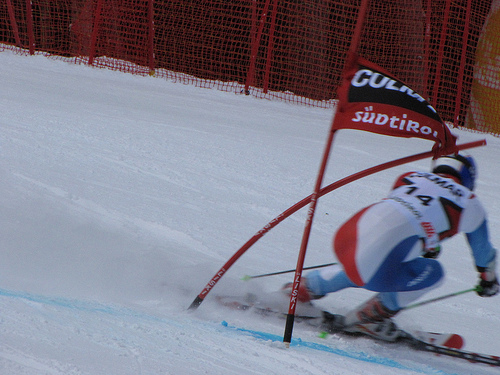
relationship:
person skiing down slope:
[264, 150, 499, 346] [4, 45, 499, 373]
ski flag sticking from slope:
[259, 3, 460, 343] [4, 45, 499, 373]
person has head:
[264, 150, 499, 346] [429, 148, 479, 192]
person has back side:
[264, 150, 499, 346] [332, 217, 409, 294]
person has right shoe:
[264, 150, 499, 346] [345, 301, 402, 341]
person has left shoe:
[264, 150, 499, 346] [280, 278, 319, 318]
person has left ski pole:
[264, 150, 499, 346] [244, 245, 341, 298]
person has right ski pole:
[264, 150, 499, 346] [321, 280, 481, 337]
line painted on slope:
[2, 283, 411, 372] [4, 45, 499, 373]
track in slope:
[11, 165, 230, 271] [4, 45, 499, 373]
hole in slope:
[142, 297, 167, 313] [4, 45, 499, 373]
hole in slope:
[47, 357, 62, 371] [4, 45, 499, 373]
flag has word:
[334, 54, 457, 155] [353, 101, 443, 140]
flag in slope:
[334, 54, 457, 155] [4, 45, 499, 373]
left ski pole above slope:
[244, 245, 341, 298] [4, 45, 499, 373]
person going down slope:
[264, 150, 499, 346] [4, 45, 499, 373]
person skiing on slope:
[264, 150, 499, 346] [4, 45, 499, 373]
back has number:
[391, 169, 480, 239] [408, 182, 435, 210]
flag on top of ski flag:
[334, 54, 457, 155] [259, 3, 460, 343]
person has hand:
[264, 150, 499, 346] [476, 281, 500, 297]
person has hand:
[264, 150, 499, 346] [425, 246, 441, 259]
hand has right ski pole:
[476, 281, 500, 297] [321, 280, 481, 337]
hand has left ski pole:
[425, 246, 441, 259] [244, 245, 341, 298]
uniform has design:
[301, 170, 496, 316] [368, 235, 442, 294]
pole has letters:
[188, 135, 490, 315] [199, 267, 226, 302]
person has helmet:
[264, 150, 499, 346] [433, 150, 477, 190]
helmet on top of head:
[433, 150, 477, 190] [429, 148, 479, 192]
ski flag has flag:
[259, 3, 460, 343] [334, 54, 457, 155]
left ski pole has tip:
[244, 245, 341, 298] [242, 274, 253, 284]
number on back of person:
[408, 182, 435, 210] [264, 150, 499, 346]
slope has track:
[4, 45, 499, 373] [11, 165, 230, 271]